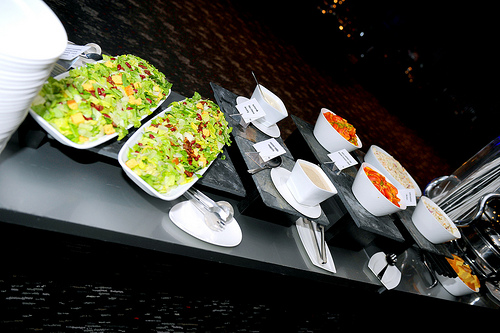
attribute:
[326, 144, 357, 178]
paper — white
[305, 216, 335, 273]
napkins — white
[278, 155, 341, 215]
cup — white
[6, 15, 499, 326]
table — long, gray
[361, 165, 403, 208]
food — orang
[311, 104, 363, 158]
bowl — white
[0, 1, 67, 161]
plates — white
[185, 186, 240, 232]
tongs — silver